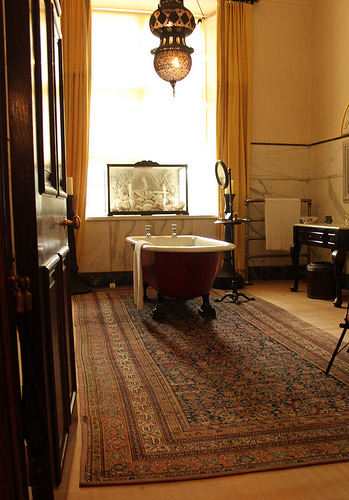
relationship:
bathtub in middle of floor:
[127, 234, 236, 328] [64, 276, 348, 491]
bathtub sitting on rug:
[127, 234, 236, 328] [60, 278, 348, 490]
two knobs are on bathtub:
[136, 217, 190, 244] [127, 234, 236, 328]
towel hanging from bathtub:
[129, 236, 151, 309] [127, 234, 236, 328]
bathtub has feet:
[127, 234, 236, 328] [143, 294, 220, 329]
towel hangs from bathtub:
[129, 236, 151, 309] [127, 234, 236, 328]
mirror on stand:
[211, 158, 234, 190] [213, 193, 254, 303]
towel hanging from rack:
[259, 189, 305, 259] [240, 184, 318, 289]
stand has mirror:
[213, 193, 254, 303] [211, 158, 234, 190]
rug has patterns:
[60, 278, 348, 490] [75, 378, 250, 403]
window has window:
[79, 9, 212, 226] [79, 13, 216, 215]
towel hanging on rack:
[129, 236, 151, 309] [240, 184, 318, 289]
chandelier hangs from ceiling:
[112, 1, 234, 112] [7, 4, 348, 30]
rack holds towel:
[240, 184, 318, 289] [259, 189, 305, 259]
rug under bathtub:
[60, 278, 348, 490] [127, 234, 236, 328]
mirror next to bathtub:
[211, 158, 234, 190] [127, 234, 236, 328]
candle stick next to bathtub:
[215, 177, 250, 220] [127, 234, 236, 328]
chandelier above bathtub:
[112, 1, 234, 112] [127, 234, 236, 328]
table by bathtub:
[283, 204, 348, 309] [127, 234, 236, 328]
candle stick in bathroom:
[215, 177, 250, 220] [0, 3, 348, 495]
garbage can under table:
[292, 253, 344, 300] [283, 204, 348, 309]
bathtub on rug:
[127, 234, 236, 328] [60, 278, 348, 490]